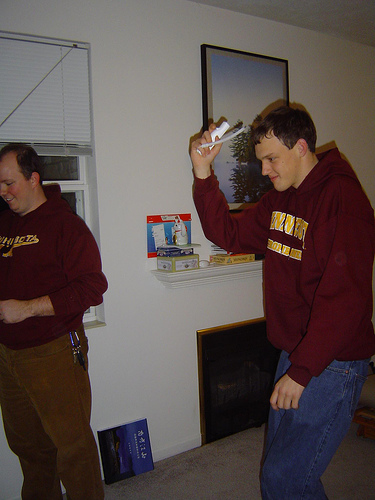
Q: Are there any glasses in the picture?
A: No, there are no glasses.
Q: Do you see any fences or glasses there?
A: No, there are no glasses or fences.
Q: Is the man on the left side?
A: Yes, the man is on the left of the image.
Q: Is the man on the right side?
A: No, the man is on the left of the image.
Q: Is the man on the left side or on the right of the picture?
A: The man is on the left of the image.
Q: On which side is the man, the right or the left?
A: The man is on the left of the image.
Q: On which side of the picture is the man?
A: The man is on the left of the image.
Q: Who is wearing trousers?
A: The man is wearing trousers.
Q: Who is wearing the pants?
A: The man is wearing trousers.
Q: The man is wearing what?
A: The man is wearing pants.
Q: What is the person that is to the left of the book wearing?
A: The man is wearing pants.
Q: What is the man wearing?
A: The man is wearing pants.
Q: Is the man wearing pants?
A: Yes, the man is wearing pants.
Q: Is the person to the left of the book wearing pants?
A: Yes, the man is wearing pants.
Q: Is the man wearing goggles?
A: No, the man is wearing pants.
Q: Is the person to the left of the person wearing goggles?
A: No, the man is wearing pants.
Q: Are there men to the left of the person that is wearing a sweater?
A: Yes, there is a man to the left of the person.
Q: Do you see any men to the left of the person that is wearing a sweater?
A: Yes, there is a man to the left of the person.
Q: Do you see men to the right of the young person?
A: No, the man is to the left of the person.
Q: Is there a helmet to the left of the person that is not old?
A: No, there is a man to the left of the person.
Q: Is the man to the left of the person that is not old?
A: Yes, the man is to the left of the person.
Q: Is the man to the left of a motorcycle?
A: No, the man is to the left of the person.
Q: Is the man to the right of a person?
A: No, the man is to the left of a person.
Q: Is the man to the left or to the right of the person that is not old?
A: The man is to the left of the person.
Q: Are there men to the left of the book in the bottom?
A: Yes, there is a man to the left of the book.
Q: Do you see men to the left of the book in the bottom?
A: Yes, there is a man to the left of the book.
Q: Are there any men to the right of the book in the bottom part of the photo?
A: No, the man is to the left of the book.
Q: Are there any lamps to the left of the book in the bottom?
A: No, there is a man to the left of the book.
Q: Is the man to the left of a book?
A: Yes, the man is to the left of a book.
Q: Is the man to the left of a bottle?
A: No, the man is to the left of a book.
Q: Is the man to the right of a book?
A: No, the man is to the left of a book.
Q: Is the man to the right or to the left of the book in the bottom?
A: The man is to the left of the book.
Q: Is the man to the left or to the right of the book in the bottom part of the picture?
A: The man is to the left of the book.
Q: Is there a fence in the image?
A: No, there are no fences.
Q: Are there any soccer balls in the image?
A: No, there are no soccer balls.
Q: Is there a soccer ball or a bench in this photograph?
A: No, there are no soccer balls or benches.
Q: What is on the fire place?
A: The book is on the fire place.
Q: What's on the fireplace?
A: The book is on the fire place.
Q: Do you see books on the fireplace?
A: Yes, there is a book on the fireplace.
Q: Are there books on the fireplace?
A: Yes, there is a book on the fireplace.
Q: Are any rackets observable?
A: No, there are no rackets.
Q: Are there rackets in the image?
A: No, there are no rackets.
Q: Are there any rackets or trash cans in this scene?
A: No, there are no rackets or trash cans.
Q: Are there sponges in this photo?
A: No, there are no sponges.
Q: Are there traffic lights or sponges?
A: No, there are no sponges or traffic lights.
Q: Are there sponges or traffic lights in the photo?
A: No, there are no sponges or traffic lights.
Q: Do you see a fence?
A: No, there are no fences.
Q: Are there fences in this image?
A: No, there are no fences.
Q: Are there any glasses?
A: No, there are no glasses.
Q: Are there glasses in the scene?
A: No, there are no glasses.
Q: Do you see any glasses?
A: No, there are no glasses.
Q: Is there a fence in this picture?
A: No, there are no fences.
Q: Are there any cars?
A: No, there are no cars.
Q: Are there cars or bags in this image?
A: No, there are no cars or bags.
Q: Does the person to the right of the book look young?
A: Yes, the person is young.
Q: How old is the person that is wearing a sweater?
A: The person is young.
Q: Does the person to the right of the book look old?
A: No, the person is young.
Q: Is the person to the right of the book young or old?
A: The person is young.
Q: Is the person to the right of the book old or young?
A: The person is young.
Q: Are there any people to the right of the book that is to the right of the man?
A: Yes, there is a person to the right of the book.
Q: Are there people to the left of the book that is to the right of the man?
A: No, the person is to the right of the book.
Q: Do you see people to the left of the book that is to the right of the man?
A: No, the person is to the right of the book.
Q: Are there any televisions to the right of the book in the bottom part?
A: No, there is a person to the right of the book.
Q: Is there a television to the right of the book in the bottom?
A: No, there is a person to the right of the book.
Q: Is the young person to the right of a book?
A: Yes, the person is to the right of a book.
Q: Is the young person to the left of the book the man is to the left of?
A: No, the person is to the right of the book.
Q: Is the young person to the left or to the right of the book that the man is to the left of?
A: The person is to the right of the book.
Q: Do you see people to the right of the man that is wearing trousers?
A: Yes, there is a person to the right of the man.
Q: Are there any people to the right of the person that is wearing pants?
A: Yes, there is a person to the right of the man.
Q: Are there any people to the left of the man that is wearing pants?
A: No, the person is to the right of the man.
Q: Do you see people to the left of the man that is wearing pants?
A: No, the person is to the right of the man.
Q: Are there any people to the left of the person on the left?
A: No, the person is to the right of the man.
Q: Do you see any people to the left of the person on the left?
A: No, the person is to the right of the man.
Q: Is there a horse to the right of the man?
A: No, there is a person to the right of the man.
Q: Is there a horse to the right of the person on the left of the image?
A: No, there is a person to the right of the man.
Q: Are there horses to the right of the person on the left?
A: No, there is a person to the right of the man.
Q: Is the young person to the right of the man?
A: Yes, the person is to the right of the man.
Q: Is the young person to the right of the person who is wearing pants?
A: Yes, the person is to the right of the man.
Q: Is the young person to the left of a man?
A: No, the person is to the right of a man.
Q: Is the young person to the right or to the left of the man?
A: The person is to the right of the man.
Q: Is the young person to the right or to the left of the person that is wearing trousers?
A: The person is to the right of the man.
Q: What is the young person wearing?
A: The person is wearing a sweater.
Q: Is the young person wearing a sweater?
A: Yes, the person is wearing a sweater.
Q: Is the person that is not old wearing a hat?
A: No, the person is wearing a sweater.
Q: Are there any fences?
A: No, there are no fences.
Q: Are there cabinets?
A: No, there are no cabinets.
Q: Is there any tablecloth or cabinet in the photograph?
A: No, there are no cabinets or tablecloths.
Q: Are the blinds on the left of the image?
A: Yes, the blinds are on the left of the image.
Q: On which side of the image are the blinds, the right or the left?
A: The blinds are on the left of the image.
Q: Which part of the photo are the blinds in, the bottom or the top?
A: The blinds are in the top of the image.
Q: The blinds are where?
A: The blinds are at the window.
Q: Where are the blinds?
A: The blinds are at the window.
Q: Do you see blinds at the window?
A: Yes, there are blinds at the window.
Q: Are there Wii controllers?
A: Yes, there is a Wii controller.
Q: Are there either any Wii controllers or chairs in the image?
A: Yes, there is a Wii controller.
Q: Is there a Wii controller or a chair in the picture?
A: Yes, there is a Wii controller.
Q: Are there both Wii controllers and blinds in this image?
A: Yes, there are both a Wii controller and blinds.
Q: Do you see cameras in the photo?
A: No, there are no cameras.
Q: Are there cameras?
A: No, there are no cameras.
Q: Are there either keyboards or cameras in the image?
A: No, there are no cameras or keyboards.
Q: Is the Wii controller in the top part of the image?
A: Yes, the Wii controller is in the top of the image.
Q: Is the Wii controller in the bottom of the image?
A: No, the Wii controller is in the top of the image.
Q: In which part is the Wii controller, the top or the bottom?
A: The Wii controller is in the top of the image.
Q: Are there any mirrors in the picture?
A: No, there are no mirrors.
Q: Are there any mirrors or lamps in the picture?
A: No, there are no mirrors or lamps.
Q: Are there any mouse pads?
A: No, there are no mouse pads.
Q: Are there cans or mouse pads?
A: No, there are no mouse pads or cans.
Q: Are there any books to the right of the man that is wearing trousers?
A: Yes, there is a book to the right of the man.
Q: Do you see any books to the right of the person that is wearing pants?
A: Yes, there is a book to the right of the man.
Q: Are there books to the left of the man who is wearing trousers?
A: No, the book is to the right of the man.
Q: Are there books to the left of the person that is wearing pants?
A: No, the book is to the right of the man.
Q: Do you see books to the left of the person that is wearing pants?
A: No, the book is to the right of the man.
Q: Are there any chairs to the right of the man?
A: No, there is a book to the right of the man.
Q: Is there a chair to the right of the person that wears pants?
A: No, there is a book to the right of the man.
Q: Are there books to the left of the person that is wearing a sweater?
A: Yes, there is a book to the left of the person.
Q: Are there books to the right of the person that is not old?
A: No, the book is to the left of the person.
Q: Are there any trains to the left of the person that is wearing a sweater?
A: No, there is a book to the left of the person.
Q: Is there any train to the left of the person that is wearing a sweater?
A: No, there is a book to the left of the person.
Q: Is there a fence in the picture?
A: No, there are no fences.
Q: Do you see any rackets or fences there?
A: No, there are no fences or rackets.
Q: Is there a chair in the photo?
A: No, there are no chairs.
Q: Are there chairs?
A: No, there are no chairs.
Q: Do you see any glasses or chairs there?
A: No, there are no chairs or glasses.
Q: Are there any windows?
A: Yes, there is a window.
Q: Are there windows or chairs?
A: Yes, there is a window.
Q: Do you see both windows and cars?
A: No, there is a window but no cars.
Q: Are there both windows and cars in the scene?
A: No, there is a window but no cars.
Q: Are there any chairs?
A: No, there are no chairs.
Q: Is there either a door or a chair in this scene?
A: No, there are no chairs or doors.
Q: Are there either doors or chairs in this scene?
A: No, there are no chairs or doors.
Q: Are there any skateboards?
A: No, there are no skateboards.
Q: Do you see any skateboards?
A: No, there are no skateboards.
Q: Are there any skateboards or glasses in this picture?
A: No, there are no skateboards or glasses.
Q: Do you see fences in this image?
A: No, there are no fences.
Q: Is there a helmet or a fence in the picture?
A: No, there are no fences or helmets.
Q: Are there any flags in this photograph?
A: No, there are no flags.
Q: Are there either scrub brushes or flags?
A: No, there are no flags or scrub brushes.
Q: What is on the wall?
A: The picture is on the wall.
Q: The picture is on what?
A: The picture is on the wall.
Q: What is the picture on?
A: The picture is on the wall.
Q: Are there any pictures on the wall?
A: Yes, there is a picture on the wall.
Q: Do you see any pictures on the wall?
A: Yes, there is a picture on the wall.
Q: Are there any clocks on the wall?
A: No, there is a picture on the wall.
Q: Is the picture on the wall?
A: Yes, the picture is on the wall.